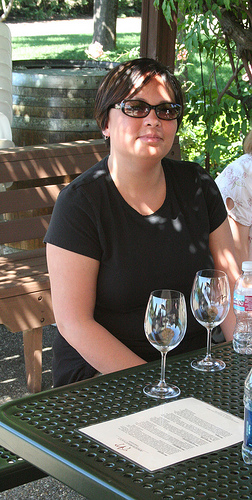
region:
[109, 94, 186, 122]
black sunglasses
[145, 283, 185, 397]
a clear wine glass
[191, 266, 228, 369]
a clear wine glass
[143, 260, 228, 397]
two clear wine glasses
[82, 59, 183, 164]
a woman with dark hair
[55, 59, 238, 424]
a woman sitting at a green table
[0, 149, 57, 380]
a brown wooden bench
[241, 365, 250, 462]
a water bottle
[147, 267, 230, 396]
two empty wine glasses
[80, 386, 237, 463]
a menu on a green plastic table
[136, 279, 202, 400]
wine glass on table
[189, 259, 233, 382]
wine glass on table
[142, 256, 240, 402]
two wine glasses on table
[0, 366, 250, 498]
green table and bench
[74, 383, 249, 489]
menu card on table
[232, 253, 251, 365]
bottle of water on table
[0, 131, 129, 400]
brown wooden bench in back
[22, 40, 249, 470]
woman sitting at table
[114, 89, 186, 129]
woman wearing black sunglases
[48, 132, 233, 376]
woman wearing a black shirt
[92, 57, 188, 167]
A woman with dark brown hair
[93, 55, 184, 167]
A woman with a short hair cut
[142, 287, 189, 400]
An empty glass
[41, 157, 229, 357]
A woman's black top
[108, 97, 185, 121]
A woman's sun glasses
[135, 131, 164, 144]
A woman's lips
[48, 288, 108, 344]
A woman's elbow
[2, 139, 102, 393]
A brown wooden bench behind a woman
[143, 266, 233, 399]
Two empty glasses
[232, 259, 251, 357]
A bottle of water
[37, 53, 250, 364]
a woman sitting at a table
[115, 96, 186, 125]
a woman wearing sunglasses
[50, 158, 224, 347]
a woman wearing a black shirt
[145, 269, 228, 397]
two glasses on a table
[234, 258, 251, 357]
a water bottle on a table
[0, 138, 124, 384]
a brown bench behind a woman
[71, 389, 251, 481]
a paper laying on the table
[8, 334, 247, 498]
a table with holes in it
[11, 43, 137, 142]
a barrel behind a woman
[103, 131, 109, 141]
an earing on a woman